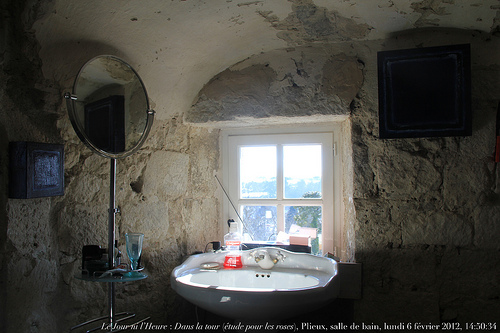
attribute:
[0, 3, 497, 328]
wall — cement, stone, raw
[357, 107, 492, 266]
wall — cement, block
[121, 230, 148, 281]
glass — blue, clear, pale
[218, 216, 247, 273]
bottle — plastic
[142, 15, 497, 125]
ceiling — round, cement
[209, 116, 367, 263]
window — white, wooden, painted, small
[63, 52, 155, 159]
mirror — large, round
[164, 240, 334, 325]
basin — sink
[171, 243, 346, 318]
sink — white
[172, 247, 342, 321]
sink — white, pedestal, ceramic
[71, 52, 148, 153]
mirror — circular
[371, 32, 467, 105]
speaker — large, black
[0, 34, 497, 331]
wall — stones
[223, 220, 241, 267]
bottle — soap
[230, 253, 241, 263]
soap — liquid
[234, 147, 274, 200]
pane — four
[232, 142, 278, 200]
pane — glass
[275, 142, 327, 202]
pane — glass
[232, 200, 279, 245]
pane — glass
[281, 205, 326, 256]
pane — glass